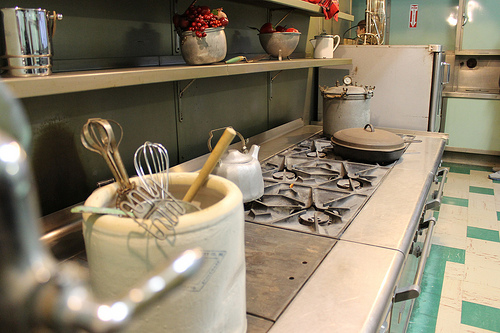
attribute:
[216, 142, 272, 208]
tea kettle — silver, aluminum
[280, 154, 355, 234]
iron burners — old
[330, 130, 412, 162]
pan — cast iron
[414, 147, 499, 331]
floor tiles — green and white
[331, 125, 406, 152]
lid — cast iron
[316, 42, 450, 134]
refrigerator — old, white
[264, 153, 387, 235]
burner — gas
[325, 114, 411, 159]
pan — cat iron